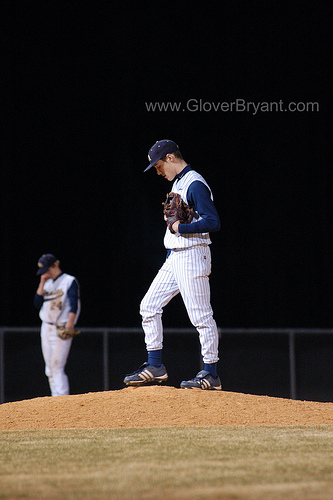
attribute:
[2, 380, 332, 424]
pitcher's mound — dirt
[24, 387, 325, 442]
dirt — in a mound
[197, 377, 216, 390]
logo — three stripes, adidas logo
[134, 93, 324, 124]
lettering — website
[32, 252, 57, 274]
cap — white, black, a baseball cap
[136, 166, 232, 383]
uniform — blue, white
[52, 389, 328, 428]
hill — dirt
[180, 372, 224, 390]
shoe — black, white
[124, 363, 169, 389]
shoe — black, white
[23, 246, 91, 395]
player — in far view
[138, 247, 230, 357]
pants — white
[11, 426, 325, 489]
grass — green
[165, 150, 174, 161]
ear — left ear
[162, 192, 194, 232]
mitt — leather, brown, catcher's mitt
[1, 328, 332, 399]
fence — metal, tall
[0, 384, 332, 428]
mound — dirt, pitcher's mound, a picther's mound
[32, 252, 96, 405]
men — looking down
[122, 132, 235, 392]
men — looking down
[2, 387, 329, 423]
dirt — brown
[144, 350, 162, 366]
sock — blue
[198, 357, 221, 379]
sock — blue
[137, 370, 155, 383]
logo — three stripes, adidas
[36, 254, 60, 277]
head — tilting